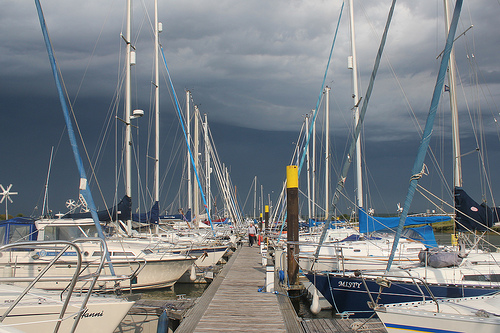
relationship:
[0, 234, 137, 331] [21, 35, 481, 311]
boat at marina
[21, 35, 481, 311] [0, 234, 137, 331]
marina with many boat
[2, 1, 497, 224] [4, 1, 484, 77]
sky has cloud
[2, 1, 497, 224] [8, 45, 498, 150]
sky has cloud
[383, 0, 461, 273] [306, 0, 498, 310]
sail on boat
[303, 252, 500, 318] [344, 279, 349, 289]
boat has letter i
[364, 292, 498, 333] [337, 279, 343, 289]
sailboat has letter s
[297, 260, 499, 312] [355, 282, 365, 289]
sailboat has letter y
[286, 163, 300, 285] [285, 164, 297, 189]
post has yellow top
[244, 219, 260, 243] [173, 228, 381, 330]
person on pier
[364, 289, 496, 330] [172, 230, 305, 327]
boat next to pier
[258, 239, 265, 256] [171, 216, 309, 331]
post on pier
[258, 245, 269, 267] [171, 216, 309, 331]
post on pier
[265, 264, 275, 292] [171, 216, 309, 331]
post on pier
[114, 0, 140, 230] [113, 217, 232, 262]
mast on boat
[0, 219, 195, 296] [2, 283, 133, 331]
boat near boat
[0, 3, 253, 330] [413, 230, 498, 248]
boats on water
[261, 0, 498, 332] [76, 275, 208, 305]
boats on water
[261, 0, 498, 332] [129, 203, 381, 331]
boats docked at pier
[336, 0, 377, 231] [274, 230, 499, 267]
pole sticking out of boat